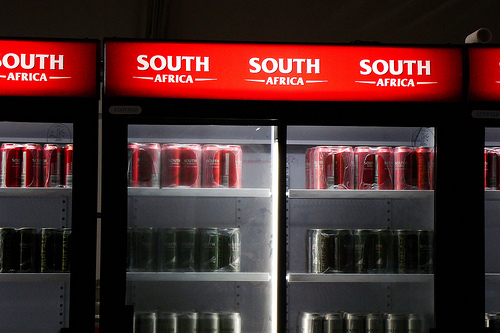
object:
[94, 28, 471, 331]
fridge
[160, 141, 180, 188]
drinks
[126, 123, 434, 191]
top row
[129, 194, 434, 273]
second shelf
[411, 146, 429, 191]
cans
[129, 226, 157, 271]
cans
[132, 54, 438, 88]
lettering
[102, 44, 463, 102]
background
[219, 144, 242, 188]
can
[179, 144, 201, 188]
can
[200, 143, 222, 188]
can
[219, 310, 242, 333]
can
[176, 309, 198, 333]
can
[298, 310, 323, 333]
can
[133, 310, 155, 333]
cans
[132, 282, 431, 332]
bottom shelf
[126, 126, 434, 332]
rear surface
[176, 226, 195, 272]
can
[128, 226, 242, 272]
wrapper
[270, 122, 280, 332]
tube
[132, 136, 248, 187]
light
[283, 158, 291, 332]
holes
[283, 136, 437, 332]
wall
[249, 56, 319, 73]
word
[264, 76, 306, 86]
word